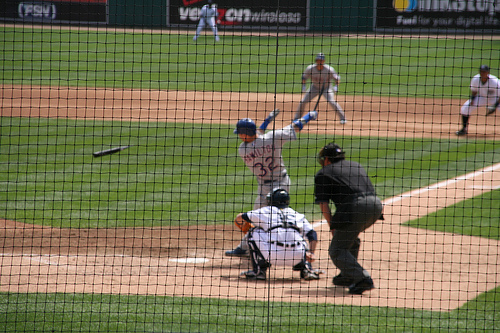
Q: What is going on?
A: Baseball game.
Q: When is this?
A: During the game.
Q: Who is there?
A: Baseball players.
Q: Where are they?
A: Baseball diamond.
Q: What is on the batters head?
A: Helmet.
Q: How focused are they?
A: Completely.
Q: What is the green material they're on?
A: AstroTurf.